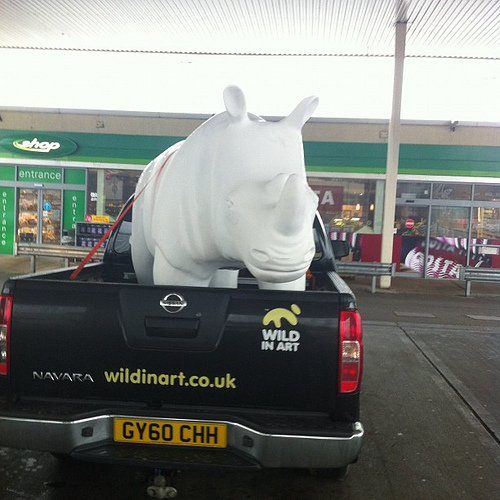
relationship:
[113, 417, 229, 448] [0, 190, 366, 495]
license on truck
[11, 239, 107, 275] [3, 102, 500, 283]
railing in front of store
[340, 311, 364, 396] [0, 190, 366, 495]
tail light on truck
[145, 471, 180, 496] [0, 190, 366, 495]
hitch on truck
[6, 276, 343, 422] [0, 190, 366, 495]
tail gate on truck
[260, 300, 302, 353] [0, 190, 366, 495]
logo on truck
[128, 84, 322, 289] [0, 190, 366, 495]
rhino in truck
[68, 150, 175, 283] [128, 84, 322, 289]
strap on rhino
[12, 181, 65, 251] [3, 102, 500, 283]
door on store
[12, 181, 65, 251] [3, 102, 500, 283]
door to store